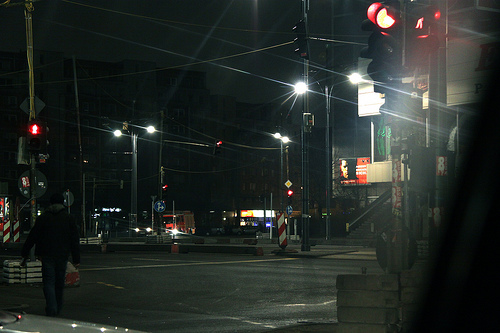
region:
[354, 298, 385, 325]
part of a brick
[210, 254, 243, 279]
part of a road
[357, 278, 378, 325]
dge of a brick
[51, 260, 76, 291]
part of a trouser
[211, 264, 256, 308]
par of a road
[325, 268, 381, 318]
part of a brick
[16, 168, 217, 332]
a man walking across the street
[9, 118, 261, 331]
a man crossing the street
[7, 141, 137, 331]
a man wearing a jacket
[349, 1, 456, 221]
a red traffic light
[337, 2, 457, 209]
a red traffic light on a pole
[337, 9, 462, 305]
a red traffic light on a metal pole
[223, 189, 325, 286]
a red and white street sign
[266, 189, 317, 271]
a red and white caution sign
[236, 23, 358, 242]
a street light on a pole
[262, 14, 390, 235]
a street light on a metal pole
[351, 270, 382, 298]
part of a brick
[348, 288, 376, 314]
part of a brick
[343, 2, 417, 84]
the light is red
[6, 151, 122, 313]
person standing on the corner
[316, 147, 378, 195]
a billboard in the background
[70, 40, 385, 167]
the street lamps are on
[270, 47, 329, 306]
the light is on a pole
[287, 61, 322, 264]
the pole is black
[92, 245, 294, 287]
the lines on the street are white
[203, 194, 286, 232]
a corner store in the distance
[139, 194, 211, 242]
a red truck in the background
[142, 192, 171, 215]
a sign with arrows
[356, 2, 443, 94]
traffic signal with lights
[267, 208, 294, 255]
caution flags on street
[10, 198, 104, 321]
person crossing street at night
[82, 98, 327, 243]
overhead lines under street lamps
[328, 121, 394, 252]
billboard on side of building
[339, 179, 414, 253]
staircase with balustrade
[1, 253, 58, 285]
cement barriers on roadway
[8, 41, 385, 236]
buildings with dark windows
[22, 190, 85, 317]
person wearing jacket on street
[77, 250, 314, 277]
painted lines on street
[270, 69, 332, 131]
the light is bright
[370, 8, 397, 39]
the light is red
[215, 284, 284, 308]
the street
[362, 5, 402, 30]
a red light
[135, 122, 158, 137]
the street light is white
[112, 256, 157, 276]
a line in the street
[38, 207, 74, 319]
a person standing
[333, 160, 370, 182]
a poster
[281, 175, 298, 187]
a yellow sign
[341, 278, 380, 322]
bricks of concrete